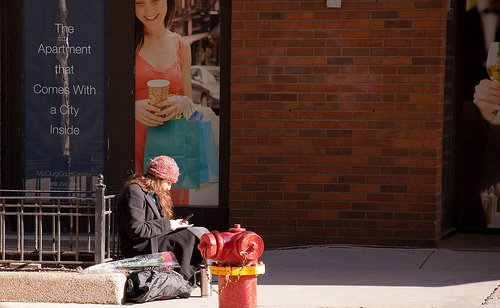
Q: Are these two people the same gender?
A: Yes, all the people are female.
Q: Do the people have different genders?
A: No, all the people are female.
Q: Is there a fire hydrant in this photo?
A: Yes, there is a fire hydrant.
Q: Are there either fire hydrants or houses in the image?
A: Yes, there is a fire hydrant.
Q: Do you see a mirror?
A: No, there are no mirrors.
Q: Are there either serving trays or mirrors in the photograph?
A: No, there are no mirrors or serving trays.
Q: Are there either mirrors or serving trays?
A: No, there are no mirrors or serving trays.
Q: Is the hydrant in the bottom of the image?
A: Yes, the hydrant is in the bottom of the image.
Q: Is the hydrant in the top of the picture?
A: No, the hydrant is in the bottom of the image.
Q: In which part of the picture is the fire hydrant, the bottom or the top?
A: The fire hydrant is in the bottom of the image.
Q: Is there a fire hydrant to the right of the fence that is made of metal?
A: Yes, there is a fire hydrant to the right of the fence.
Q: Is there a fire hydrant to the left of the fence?
A: No, the fire hydrant is to the right of the fence.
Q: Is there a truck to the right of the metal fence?
A: No, there is a fire hydrant to the right of the fence.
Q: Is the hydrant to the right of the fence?
A: Yes, the hydrant is to the right of the fence.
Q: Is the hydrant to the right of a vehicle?
A: No, the hydrant is to the right of the fence.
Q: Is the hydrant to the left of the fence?
A: No, the hydrant is to the right of the fence.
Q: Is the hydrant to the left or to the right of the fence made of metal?
A: The hydrant is to the right of the fence.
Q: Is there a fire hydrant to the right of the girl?
A: Yes, there is a fire hydrant to the right of the girl.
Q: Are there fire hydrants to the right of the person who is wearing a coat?
A: Yes, there is a fire hydrant to the right of the girl.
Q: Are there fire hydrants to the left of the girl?
A: No, the fire hydrant is to the right of the girl.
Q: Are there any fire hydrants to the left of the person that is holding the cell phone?
A: No, the fire hydrant is to the right of the girl.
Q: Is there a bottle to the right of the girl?
A: No, there is a fire hydrant to the right of the girl.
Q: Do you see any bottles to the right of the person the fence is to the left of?
A: No, there is a fire hydrant to the right of the girl.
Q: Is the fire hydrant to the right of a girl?
A: Yes, the fire hydrant is to the right of a girl.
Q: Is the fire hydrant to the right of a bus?
A: No, the fire hydrant is to the right of a girl.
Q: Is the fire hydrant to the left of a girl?
A: No, the fire hydrant is to the right of a girl.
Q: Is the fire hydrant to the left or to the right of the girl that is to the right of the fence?
A: The fire hydrant is to the right of the girl.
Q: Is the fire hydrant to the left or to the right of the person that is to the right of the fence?
A: The fire hydrant is to the right of the girl.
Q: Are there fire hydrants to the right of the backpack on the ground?
A: Yes, there is a fire hydrant to the right of the backpack.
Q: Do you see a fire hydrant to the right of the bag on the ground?
A: Yes, there is a fire hydrant to the right of the backpack.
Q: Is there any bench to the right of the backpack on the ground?
A: No, there is a fire hydrant to the right of the backpack.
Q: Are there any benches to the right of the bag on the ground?
A: No, there is a fire hydrant to the right of the backpack.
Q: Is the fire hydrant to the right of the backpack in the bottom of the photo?
A: Yes, the fire hydrant is to the right of the backpack.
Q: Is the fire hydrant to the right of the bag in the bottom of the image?
A: Yes, the fire hydrant is to the right of the backpack.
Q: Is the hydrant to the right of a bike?
A: No, the hydrant is to the right of the backpack.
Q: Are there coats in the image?
A: Yes, there is a coat.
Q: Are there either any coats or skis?
A: Yes, there is a coat.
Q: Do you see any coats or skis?
A: Yes, there is a coat.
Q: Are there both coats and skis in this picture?
A: No, there is a coat but no skis.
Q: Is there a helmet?
A: No, there are no helmets.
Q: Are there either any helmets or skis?
A: No, there are no helmets or skis.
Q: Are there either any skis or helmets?
A: No, there are no helmets or skis.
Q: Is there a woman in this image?
A: Yes, there is a woman.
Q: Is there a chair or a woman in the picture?
A: Yes, there is a woman.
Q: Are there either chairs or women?
A: Yes, there is a woman.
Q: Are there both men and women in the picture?
A: No, there is a woman but no men.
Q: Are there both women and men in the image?
A: No, there is a woman but no men.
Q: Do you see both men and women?
A: No, there is a woman but no men.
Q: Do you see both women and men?
A: No, there is a woman but no men.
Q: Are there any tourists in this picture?
A: No, there are no tourists.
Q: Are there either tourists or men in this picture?
A: No, there are no tourists or men.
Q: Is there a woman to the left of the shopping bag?
A: Yes, there is a woman to the left of the shopping bag.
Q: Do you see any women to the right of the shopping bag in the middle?
A: No, the woman is to the left of the shopping bag.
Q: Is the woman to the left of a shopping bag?
A: Yes, the woman is to the left of a shopping bag.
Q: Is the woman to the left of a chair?
A: No, the woman is to the left of a shopping bag.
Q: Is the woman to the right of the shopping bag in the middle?
A: No, the woman is to the left of the shopping bag.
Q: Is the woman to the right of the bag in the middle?
A: No, the woman is to the left of the shopping bag.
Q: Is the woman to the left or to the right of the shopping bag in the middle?
A: The woman is to the left of the shopping bag.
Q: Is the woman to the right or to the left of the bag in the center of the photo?
A: The woman is to the left of the shopping bag.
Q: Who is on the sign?
A: The woman is on the sign.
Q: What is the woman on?
A: The woman is on the sign.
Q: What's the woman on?
A: The woman is on the sign.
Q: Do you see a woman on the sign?
A: Yes, there is a woman on the sign.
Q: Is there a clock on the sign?
A: No, there is a woman on the sign.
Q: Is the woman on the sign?
A: Yes, the woman is on the sign.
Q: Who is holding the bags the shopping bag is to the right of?
A: The woman is holding the bags.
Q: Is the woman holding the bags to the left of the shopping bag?
A: Yes, the woman is holding the bags.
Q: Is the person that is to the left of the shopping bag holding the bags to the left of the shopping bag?
A: Yes, the woman is holding the bags.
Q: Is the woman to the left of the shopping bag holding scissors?
A: No, the woman is holding the bags.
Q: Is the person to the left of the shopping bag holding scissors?
A: No, the woman is holding the bags.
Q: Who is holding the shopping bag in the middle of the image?
A: The woman is holding the shopping bag.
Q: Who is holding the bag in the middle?
A: The woman is holding the shopping bag.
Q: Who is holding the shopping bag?
A: The woman is holding the shopping bag.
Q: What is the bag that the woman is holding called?
A: The bag is a shopping bag.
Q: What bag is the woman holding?
A: The woman is holding the shopping bag.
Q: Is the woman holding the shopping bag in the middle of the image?
A: Yes, the woman is holding the shopping bag.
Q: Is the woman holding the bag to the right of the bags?
A: Yes, the woman is holding the shopping bag.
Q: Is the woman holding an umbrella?
A: No, the woman is holding the shopping bag.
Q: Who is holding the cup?
A: The woman is holding the cup.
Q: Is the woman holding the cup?
A: Yes, the woman is holding the cup.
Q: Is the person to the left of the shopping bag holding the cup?
A: Yes, the woman is holding the cup.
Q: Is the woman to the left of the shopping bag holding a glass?
A: No, the woman is holding the cup.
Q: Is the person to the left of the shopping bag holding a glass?
A: No, the woman is holding the cup.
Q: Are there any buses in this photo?
A: No, there are no buses.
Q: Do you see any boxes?
A: No, there are no boxes.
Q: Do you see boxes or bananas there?
A: No, there are no boxes or bananas.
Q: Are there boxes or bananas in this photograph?
A: No, there are no boxes or bananas.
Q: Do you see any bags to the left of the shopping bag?
A: Yes, there are bags to the left of the shopping bag.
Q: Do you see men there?
A: No, there are no men.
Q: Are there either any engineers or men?
A: No, there are no men or engineers.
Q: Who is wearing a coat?
A: The girl is wearing a coat.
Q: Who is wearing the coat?
A: The girl is wearing a coat.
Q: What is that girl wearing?
A: The girl is wearing a coat.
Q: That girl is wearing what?
A: The girl is wearing a coat.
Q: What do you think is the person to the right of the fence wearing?
A: The girl is wearing a coat.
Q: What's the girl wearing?
A: The girl is wearing a coat.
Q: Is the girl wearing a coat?
A: Yes, the girl is wearing a coat.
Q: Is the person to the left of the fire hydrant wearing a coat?
A: Yes, the girl is wearing a coat.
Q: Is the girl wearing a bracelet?
A: No, the girl is wearing a coat.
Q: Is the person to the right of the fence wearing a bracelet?
A: No, the girl is wearing a coat.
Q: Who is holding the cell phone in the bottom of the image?
A: The girl is holding the cellphone.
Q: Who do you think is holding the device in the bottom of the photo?
A: The girl is holding the cellphone.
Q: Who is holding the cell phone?
A: The girl is holding the cellphone.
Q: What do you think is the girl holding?
A: The girl is holding the cell phone.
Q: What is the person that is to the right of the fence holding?
A: The girl is holding the cell phone.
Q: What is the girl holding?
A: The girl is holding the cell phone.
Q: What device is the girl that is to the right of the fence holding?
A: The girl is holding the cellphone.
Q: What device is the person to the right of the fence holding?
A: The girl is holding the cellphone.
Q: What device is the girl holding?
A: The girl is holding the cellphone.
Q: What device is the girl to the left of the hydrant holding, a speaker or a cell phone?
A: The girl is holding a cell phone.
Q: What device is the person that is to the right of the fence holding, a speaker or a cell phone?
A: The girl is holding a cell phone.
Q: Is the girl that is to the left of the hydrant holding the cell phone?
A: Yes, the girl is holding the cell phone.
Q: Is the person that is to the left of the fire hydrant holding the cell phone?
A: Yes, the girl is holding the cell phone.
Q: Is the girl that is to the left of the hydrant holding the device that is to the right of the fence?
A: Yes, the girl is holding the cell phone.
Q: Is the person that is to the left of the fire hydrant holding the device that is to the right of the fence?
A: Yes, the girl is holding the cell phone.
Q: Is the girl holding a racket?
A: No, the girl is holding the cell phone.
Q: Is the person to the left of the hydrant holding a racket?
A: No, the girl is holding the cell phone.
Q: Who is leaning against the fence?
A: The girl is leaning against the fence.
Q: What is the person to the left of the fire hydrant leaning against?
A: The girl is leaning against the fence.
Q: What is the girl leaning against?
A: The girl is leaning against the fence.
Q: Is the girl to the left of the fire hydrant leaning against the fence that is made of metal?
A: Yes, the girl is leaning against the fence.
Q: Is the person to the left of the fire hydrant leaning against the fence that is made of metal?
A: Yes, the girl is leaning against the fence.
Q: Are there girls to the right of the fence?
A: Yes, there is a girl to the right of the fence.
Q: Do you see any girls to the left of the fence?
A: No, the girl is to the right of the fence.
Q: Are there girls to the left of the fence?
A: No, the girl is to the right of the fence.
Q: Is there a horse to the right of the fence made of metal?
A: No, there is a girl to the right of the fence.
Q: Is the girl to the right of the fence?
A: Yes, the girl is to the right of the fence.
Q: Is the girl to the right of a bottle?
A: No, the girl is to the right of the fence.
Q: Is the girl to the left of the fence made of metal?
A: No, the girl is to the right of the fence.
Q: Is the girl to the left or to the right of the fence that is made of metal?
A: The girl is to the right of the fence.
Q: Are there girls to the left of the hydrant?
A: Yes, there is a girl to the left of the hydrant.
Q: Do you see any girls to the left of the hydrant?
A: Yes, there is a girl to the left of the hydrant.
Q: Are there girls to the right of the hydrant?
A: No, the girl is to the left of the hydrant.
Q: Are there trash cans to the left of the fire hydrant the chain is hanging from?
A: No, there is a girl to the left of the hydrant.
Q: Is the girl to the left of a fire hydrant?
A: Yes, the girl is to the left of a fire hydrant.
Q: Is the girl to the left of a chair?
A: No, the girl is to the left of a fire hydrant.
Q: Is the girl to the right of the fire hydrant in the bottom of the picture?
A: No, the girl is to the left of the hydrant.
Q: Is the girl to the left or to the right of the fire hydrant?
A: The girl is to the left of the fire hydrant.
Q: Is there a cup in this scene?
A: Yes, there is a cup.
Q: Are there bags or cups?
A: Yes, there is a cup.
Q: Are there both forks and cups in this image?
A: No, there is a cup but no forks.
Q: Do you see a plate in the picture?
A: No, there are no plates.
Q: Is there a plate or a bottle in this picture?
A: No, there are no plates or bottles.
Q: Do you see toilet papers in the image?
A: No, there are no toilet papers.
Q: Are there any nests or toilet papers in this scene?
A: No, there are no toilet papers or nests.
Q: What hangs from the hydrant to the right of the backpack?
A: The chain hangs from the hydrant.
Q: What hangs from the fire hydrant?
A: The chain hangs from the hydrant.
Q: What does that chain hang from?
A: The chain hangs from the fire hydrant.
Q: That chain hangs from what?
A: The chain hangs from the fire hydrant.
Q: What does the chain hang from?
A: The chain hangs from the fire hydrant.